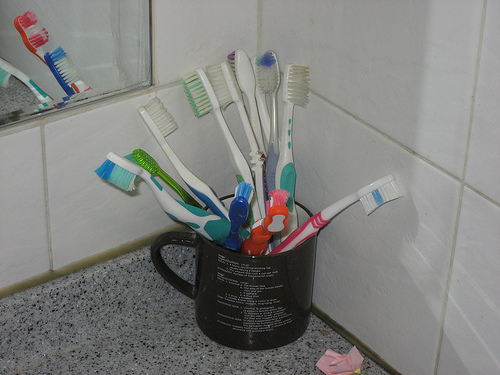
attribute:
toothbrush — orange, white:
[263, 146, 447, 281]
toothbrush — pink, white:
[267, 169, 424, 266]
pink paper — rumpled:
[313, 342, 365, 373]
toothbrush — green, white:
[276, 66, 314, 212]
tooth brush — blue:
[224, 176, 259, 253]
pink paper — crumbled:
[315, 337, 370, 374]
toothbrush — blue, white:
[222, 179, 256, 251]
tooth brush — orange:
[83, 76, 217, 238]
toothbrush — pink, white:
[290, 170, 407, 265]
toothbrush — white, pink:
[279, 64, 309, 198]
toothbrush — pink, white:
[95, 151, 230, 239]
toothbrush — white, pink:
[182, 67, 253, 187]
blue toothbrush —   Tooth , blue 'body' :
[224, 182, 254, 249]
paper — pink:
[313, 340, 368, 375]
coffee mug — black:
[149, 193, 317, 350]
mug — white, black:
[148, 192, 323, 349]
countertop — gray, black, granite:
[3, 241, 397, 373]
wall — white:
[263, 1, 499, 371]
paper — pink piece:
[312, 343, 378, 373]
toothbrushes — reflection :
[84, 47, 406, 258]